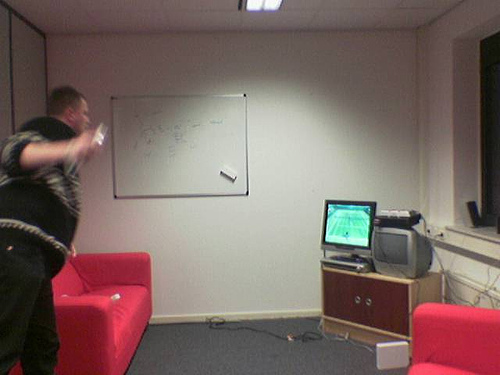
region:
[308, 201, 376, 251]
small screen on desk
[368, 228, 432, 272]
small tv on desk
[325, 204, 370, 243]
green image on screen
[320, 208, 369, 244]
tennis image on screen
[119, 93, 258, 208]
white board on wall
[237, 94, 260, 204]
silver trim on white board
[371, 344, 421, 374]
white wii system on ground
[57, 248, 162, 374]
red couch in the room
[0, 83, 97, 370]
fat man wearing black pants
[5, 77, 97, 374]
fat man with black and white sweater playing wii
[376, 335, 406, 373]
white wii console on the floor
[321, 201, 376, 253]
screen with tennis wii play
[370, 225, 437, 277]
small gray tv on a table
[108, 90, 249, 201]
white blackboard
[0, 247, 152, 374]
big red couch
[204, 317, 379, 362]
black and white cables in the floor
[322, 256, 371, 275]
black and gray dvd on a table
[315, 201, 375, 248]
small computer screen on desk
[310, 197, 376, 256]
small tv screen on desk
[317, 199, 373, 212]
thin black bezel of screen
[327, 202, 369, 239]
tennis game on screen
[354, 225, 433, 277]
small grey tv on stand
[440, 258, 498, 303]
white wires on the wall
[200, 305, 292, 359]
black wires on the ground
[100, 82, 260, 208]
white boar don the wall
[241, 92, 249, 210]
silver boarder of white board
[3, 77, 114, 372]
EXCITED PERSON PLAYING VIDEO GAME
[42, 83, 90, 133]
HEAD OF GAME PLAYER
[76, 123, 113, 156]
HAND OF GAME PLAYER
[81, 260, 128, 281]
PART OF COMFORTABLE RED COUCH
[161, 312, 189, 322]
PAR OF WHITE BASEBOARD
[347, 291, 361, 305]
HANDLE OF WOODEN CHEST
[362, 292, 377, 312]
HANDLE OF WOODEN CHEST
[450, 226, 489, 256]
PART OF WHITE WINDOW SILL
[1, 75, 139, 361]
the man is playing some kind of wii game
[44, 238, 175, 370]
the couch is pink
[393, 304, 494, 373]
the chair is pink as well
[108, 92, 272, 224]
a dry erase board is on the wall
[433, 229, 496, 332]
many wires running across the room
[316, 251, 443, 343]
the cabinet is made of wood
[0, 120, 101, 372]
the man is very heavy set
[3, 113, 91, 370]
he is all dressed in black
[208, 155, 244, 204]
the eraser for the dry board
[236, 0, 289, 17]
an overhead flurescent light is turned on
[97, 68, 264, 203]
a white board on the wall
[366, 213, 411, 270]
a tv on the stand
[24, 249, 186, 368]
a couch is red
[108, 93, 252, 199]
A whiteboard hanging on the wall.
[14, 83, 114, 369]
A man playing the wii.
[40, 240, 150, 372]
A red sofa.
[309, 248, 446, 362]
A entertainment stand.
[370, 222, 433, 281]
A grey television turned off.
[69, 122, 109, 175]
A white wii controller.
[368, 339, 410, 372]
A white Wii gaming console.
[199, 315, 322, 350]
A black cord on the floor.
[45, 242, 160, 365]
a salmon colored couch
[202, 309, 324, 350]
cords on the Rug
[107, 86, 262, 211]
A grease board on the wall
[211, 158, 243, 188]
an eraser on the grease board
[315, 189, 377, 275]
a monitor to play Wii on